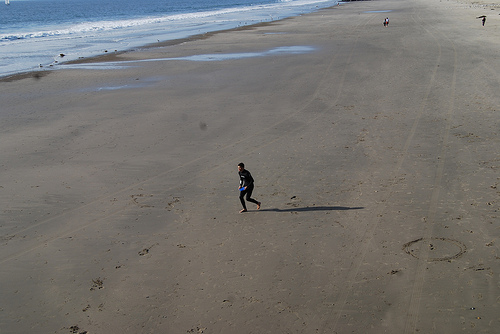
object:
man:
[238, 162, 262, 214]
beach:
[0, 0, 499, 334]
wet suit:
[237, 170, 261, 209]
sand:
[182, 104, 196, 125]